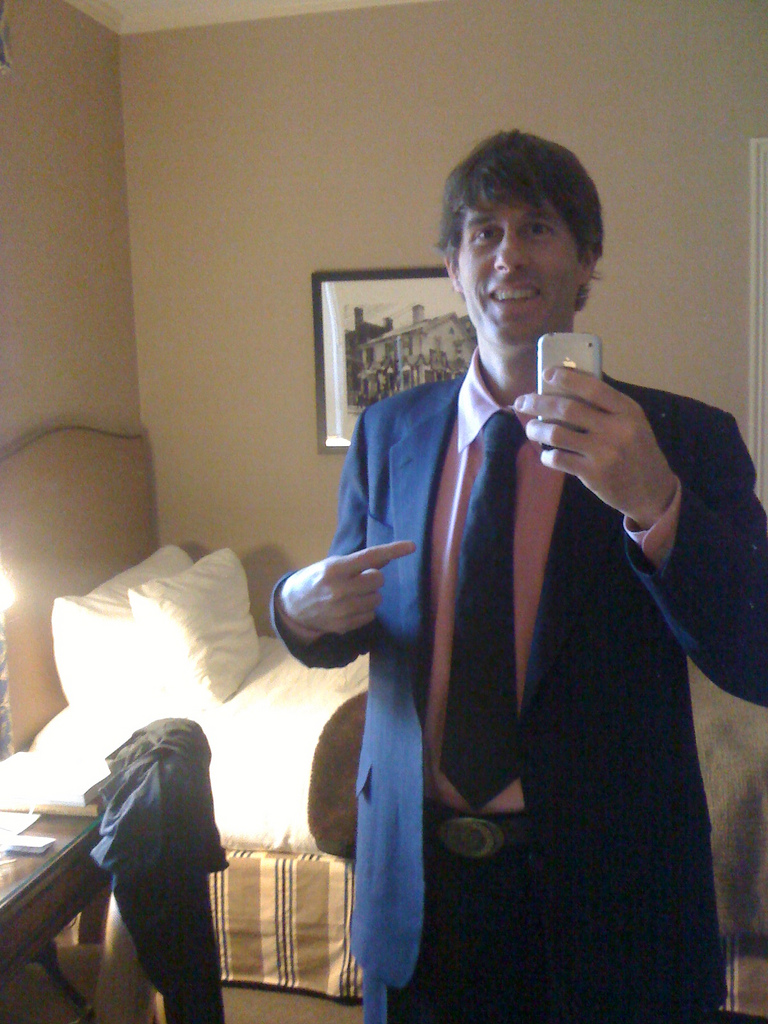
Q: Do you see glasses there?
A: No, there are no glasses.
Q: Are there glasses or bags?
A: No, there are no glasses or bags.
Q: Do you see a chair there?
A: Yes, there is a chair.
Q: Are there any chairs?
A: Yes, there is a chair.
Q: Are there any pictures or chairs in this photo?
A: Yes, there is a chair.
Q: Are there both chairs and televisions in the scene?
A: No, there is a chair but no televisions.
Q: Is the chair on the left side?
A: Yes, the chair is on the left of the image.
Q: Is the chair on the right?
A: No, the chair is on the left of the image.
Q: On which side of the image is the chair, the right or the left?
A: The chair is on the left of the image.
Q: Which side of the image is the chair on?
A: The chair is on the left of the image.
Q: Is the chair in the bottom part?
A: Yes, the chair is in the bottom of the image.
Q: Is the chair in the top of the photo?
A: No, the chair is in the bottom of the image.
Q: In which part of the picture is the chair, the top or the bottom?
A: The chair is in the bottom of the image.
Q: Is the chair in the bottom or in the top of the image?
A: The chair is in the bottom of the image.